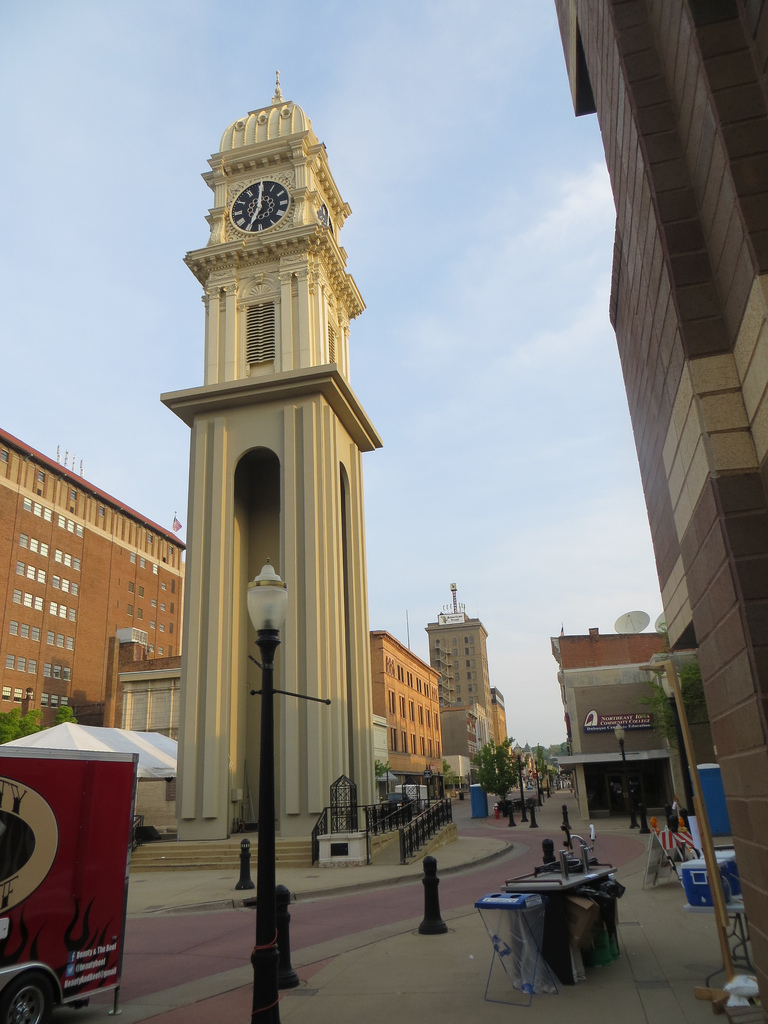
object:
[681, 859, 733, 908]
cooler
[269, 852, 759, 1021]
sidewalk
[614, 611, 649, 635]
dish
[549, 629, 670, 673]
roof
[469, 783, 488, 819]
porta pot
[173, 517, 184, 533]
flag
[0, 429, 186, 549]
roof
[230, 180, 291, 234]
clock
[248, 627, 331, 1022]
light post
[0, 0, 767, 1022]
city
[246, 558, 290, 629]
lamp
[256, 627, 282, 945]
post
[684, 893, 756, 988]
table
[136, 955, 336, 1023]
sidewalk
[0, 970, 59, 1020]
tire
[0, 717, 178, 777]
tent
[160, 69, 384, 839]
tower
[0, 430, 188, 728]
building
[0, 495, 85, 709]
windows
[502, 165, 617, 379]
clouds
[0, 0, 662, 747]
sky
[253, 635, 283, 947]
pole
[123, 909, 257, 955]
red brick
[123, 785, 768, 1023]
street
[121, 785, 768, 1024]
road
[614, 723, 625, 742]
street light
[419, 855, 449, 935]
metal pole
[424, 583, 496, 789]
building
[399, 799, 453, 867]
railing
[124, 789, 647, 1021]
pathway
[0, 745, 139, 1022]
red trailer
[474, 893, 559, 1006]
recycling can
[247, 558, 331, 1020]
lamp post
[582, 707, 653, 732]
sign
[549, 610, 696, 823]
building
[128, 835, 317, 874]
stone steps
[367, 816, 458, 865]
ramp